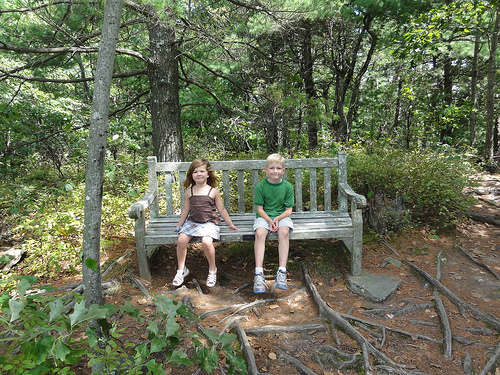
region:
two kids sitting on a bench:
[174, 154, 292, 292]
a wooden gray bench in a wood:
[129, 153, 369, 285]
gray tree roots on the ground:
[105, 245, 499, 371]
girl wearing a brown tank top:
[188, 186, 217, 221]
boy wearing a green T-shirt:
[252, 178, 294, 217]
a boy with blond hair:
[263, 154, 285, 182]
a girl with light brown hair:
[184, 158, 216, 190]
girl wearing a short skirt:
[181, 217, 221, 237]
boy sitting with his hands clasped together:
[248, 154, 295, 231]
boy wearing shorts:
[253, 212, 293, 232]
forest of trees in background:
[0, 5, 494, 129]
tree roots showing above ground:
[227, 293, 499, 373]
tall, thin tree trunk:
[78, 0, 111, 300]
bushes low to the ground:
[358, 138, 476, 230]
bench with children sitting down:
[143, 155, 365, 280]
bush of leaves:
[0, 270, 251, 372]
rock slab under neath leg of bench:
[342, 255, 401, 304]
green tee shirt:
[256, 183, 290, 214]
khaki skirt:
[178, 220, 223, 241]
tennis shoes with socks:
[248, 263, 298, 289]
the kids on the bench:
[127, 143, 364, 285]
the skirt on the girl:
[175, 214, 224, 239]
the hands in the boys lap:
[261, 212, 283, 234]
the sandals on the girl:
[175, 263, 218, 290]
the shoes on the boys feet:
[247, 263, 291, 295]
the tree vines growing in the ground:
[223, 297, 498, 372]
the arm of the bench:
[335, 179, 365, 209]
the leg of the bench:
[340, 212, 367, 276]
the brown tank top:
[183, 183, 217, 228]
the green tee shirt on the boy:
[246, 174, 300, 223]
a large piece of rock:
[338, 255, 405, 305]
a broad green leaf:
[65, 297, 111, 336]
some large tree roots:
[214, 260, 369, 365]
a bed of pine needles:
[346, 306, 487, 366]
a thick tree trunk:
[147, 70, 184, 160]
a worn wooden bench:
[127, 153, 367, 275]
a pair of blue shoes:
[251, 265, 292, 297]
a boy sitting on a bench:
[249, 151, 304, 299]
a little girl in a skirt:
[159, 154, 239, 292]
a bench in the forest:
[47, 68, 484, 363]